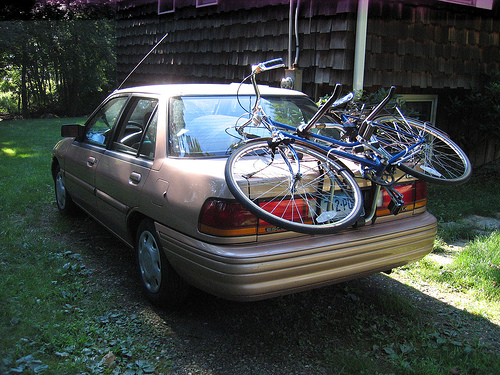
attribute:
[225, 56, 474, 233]
bike — blue, silver, tied to the car, tied to car trunk, strapped to the car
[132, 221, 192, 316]
tire — black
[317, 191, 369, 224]
license plate — blue, white, white w/blue letters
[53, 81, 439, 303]
car — small, tan, a four door sedan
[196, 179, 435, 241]
taillights — yellow, red, on the car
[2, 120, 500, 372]
grass — growing near path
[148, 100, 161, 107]
rear view mirror — located on the car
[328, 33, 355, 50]
brown wood siding — an old roof style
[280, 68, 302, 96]
utility meter — on side of the house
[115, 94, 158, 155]
window — rolled down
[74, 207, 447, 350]
gravel — on driveway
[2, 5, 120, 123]
trees — small, green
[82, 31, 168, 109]
an antenna — on windshield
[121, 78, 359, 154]
sunlight — hitting top of car